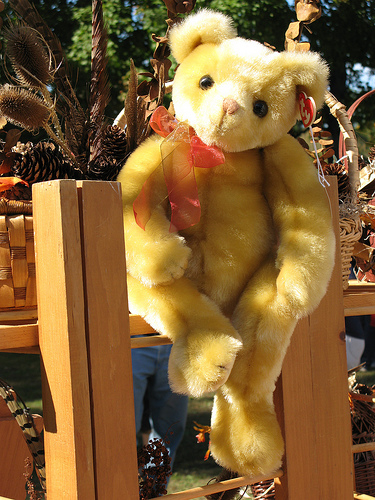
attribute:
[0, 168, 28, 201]
flowers — orange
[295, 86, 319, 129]
tag — red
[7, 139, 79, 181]
pine cone — dried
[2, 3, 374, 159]
trees — leafy, green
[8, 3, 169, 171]
bouquet — dried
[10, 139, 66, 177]
pinecone — large, brown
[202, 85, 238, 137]
nose — pink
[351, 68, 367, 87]
sky — blue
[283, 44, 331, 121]
ear — fuzzy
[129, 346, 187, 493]
jeans — light blue, denim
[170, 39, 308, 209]
teddy bear — tan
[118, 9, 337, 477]
teddy bear — big, tan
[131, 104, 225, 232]
ribbon — red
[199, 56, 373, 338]
basket — brown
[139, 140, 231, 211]
bow — red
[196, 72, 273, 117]
eyes — black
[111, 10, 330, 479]
bear — tan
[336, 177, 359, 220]
moss — Dried 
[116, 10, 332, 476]
stuffed bear — yellow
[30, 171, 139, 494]
ladder — wooden